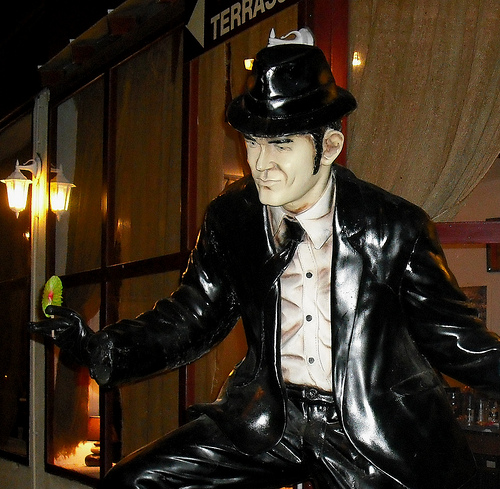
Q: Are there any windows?
A: Yes, there is a window.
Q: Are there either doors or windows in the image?
A: Yes, there is a window.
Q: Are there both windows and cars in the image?
A: No, there is a window but no cars.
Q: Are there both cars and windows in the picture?
A: No, there is a window but no cars.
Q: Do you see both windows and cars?
A: No, there is a window but no cars.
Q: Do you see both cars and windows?
A: No, there is a window but no cars.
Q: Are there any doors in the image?
A: No, there are no doors.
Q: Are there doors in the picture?
A: No, there are no doors.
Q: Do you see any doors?
A: No, there are no doors.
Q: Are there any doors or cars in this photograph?
A: No, there are no doors or cars.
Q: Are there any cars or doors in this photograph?
A: No, there are no doors or cars.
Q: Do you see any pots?
A: No, there are no pots.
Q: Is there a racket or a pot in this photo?
A: No, there are no pots or rackets.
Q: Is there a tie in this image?
A: Yes, there is a tie.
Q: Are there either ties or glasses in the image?
A: Yes, there is a tie.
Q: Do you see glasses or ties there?
A: Yes, there is a tie.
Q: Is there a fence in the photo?
A: No, there are no fences.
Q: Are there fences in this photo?
A: No, there are no fences.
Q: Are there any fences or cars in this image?
A: No, there are no fences or cars.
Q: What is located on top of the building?
A: The sign is on top of the building.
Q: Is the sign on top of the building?
A: Yes, the sign is on top of the building.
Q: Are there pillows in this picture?
A: No, there are no pillows.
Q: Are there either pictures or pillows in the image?
A: No, there are no pillows or pictures.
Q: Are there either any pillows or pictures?
A: No, there are no pillows or pictures.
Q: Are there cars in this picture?
A: No, there are no cars.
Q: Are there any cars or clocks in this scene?
A: No, there are no cars or clocks.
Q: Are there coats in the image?
A: Yes, there is a coat.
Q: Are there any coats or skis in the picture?
A: Yes, there is a coat.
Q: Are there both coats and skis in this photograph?
A: No, there is a coat but no skis.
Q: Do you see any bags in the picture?
A: No, there are no bags.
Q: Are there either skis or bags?
A: No, there are no bags or skis.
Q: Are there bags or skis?
A: No, there are no bags or skis.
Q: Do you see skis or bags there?
A: No, there are no bags or skis.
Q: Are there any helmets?
A: No, there are no helmets.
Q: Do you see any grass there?
A: Yes, there is grass.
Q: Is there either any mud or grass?
A: Yes, there is grass.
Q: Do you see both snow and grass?
A: No, there is grass but no snow.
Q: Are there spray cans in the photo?
A: No, there are no spray cans.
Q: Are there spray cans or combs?
A: No, there are no spray cans or combs.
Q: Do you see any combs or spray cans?
A: No, there are no spray cans or combs.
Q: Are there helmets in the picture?
A: No, there are no helmets.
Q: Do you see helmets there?
A: No, there are no helmets.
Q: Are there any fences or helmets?
A: No, there are no helmets or fences.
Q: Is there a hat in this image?
A: Yes, there is a hat.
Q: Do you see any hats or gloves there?
A: Yes, there is a hat.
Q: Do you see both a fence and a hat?
A: No, there is a hat but no fences.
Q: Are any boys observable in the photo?
A: No, there are no boys.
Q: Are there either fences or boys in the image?
A: No, there are no boys or fences.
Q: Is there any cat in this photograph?
A: No, there are no cats.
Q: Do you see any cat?
A: No, there are no cats.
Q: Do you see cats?
A: No, there are no cats.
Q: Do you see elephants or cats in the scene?
A: No, there are no cats or elephants.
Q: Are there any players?
A: No, there are no players.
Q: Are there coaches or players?
A: No, there are no players or coaches.